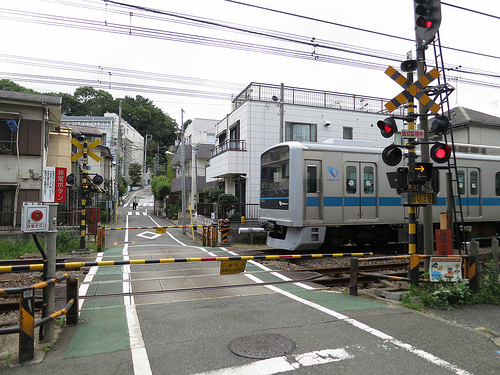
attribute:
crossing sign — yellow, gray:
[372, 55, 464, 133]